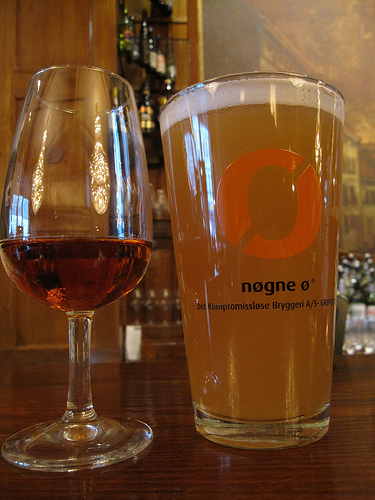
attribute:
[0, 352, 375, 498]
table — wooden